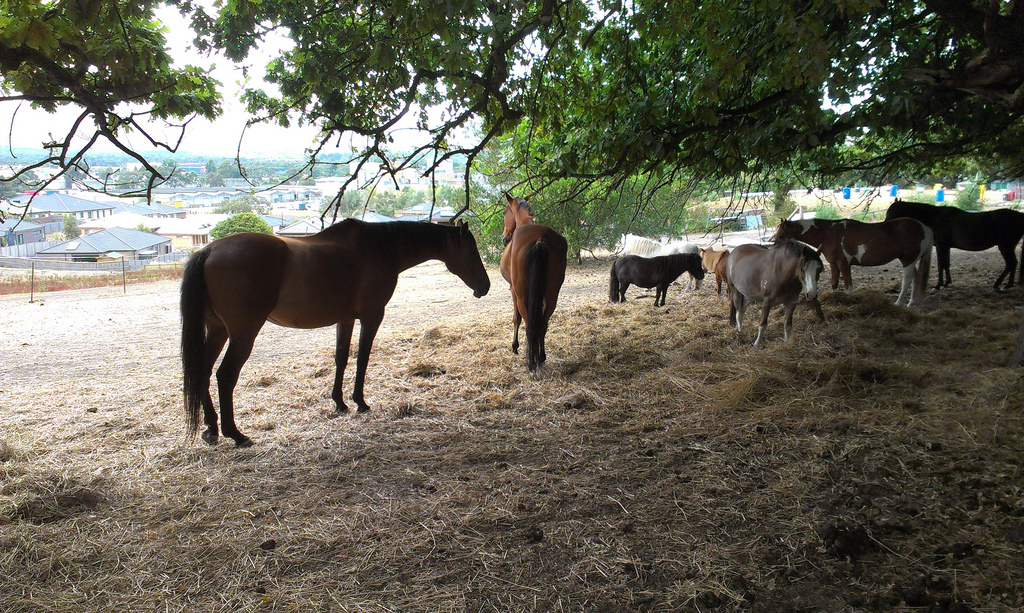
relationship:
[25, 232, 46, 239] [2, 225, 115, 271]
wall on building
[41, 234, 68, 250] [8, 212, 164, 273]
wall in building